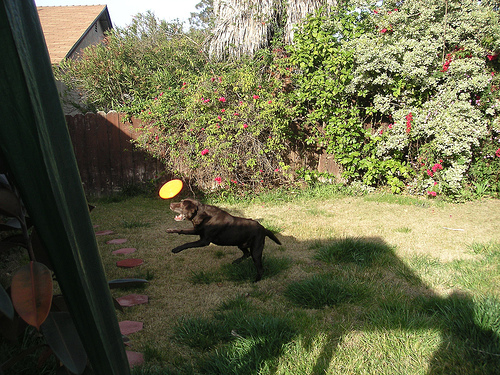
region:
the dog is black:
[163, 198, 277, 268]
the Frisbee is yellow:
[155, 162, 192, 204]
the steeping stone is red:
[112, 256, 162, 271]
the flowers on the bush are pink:
[196, 91, 248, 118]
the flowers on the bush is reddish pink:
[394, 103, 434, 136]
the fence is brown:
[93, 105, 152, 159]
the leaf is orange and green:
[6, 249, 71, 344]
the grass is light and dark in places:
[322, 200, 437, 282]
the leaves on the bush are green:
[311, 59, 343, 140]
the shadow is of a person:
[407, 262, 499, 374]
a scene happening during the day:
[5, 2, 499, 354]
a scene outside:
[3, 5, 497, 374]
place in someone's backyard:
[27, 109, 492, 371]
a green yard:
[86, 180, 498, 370]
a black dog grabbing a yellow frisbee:
[152, 168, 294, 285]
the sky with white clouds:
[85, 8, 265, 58]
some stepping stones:
[74, 185, 198, 374]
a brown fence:
[37, 82, 492, 233]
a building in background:
[14, 12, 166, 100]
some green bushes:
[78, 22, 490, 230]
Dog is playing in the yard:
[154, 167, 289, 281]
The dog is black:
[144, 168, 300, 278]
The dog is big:
[156, 172, 287, 279]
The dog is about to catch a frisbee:
[145, 167, 297, 283]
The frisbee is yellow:
[136, 163, 203, 207]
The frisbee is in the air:
[126, 154, 222, 258]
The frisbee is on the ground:
[107, 245, 153, 282]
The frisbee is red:
[111, 247, 151, 279]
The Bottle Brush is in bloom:
[136, 58, 314, 200]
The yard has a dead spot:
[282, 160, 485, 319]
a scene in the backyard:
[51, 80, 494, 373]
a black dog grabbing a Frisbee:
[133, 170, 307, 273]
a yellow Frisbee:
[151, 174, 188, 199]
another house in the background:
[32, 2, 129, 73]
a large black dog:
[160, 194, 295, 280]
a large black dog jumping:
[166, 199, 281, 268]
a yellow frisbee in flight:
[154, 177, 189, 202]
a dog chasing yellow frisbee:
[148, 169, 282, 279]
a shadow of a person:
[429, 283, 494, 373]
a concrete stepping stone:
[114, 316, 144, 339]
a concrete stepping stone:
[122, 349, 142, 371]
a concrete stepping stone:
[120, 291, 145, 311]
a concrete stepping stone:
[112, 256, 140, 268]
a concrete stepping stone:
[106, 236, 127, 243]